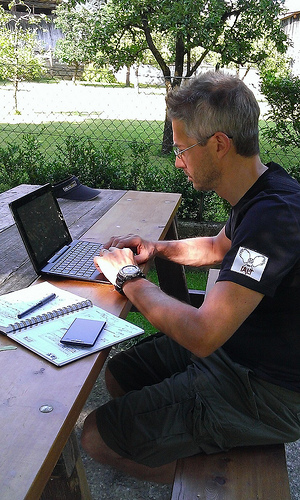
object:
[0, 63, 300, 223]
fence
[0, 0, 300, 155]
trees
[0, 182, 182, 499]
bench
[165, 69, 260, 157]
hair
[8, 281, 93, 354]
spiral notebook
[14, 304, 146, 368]
cover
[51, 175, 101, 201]
black visor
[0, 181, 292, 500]
picnic table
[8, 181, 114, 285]
laptop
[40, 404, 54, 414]
bolt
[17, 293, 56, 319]
pen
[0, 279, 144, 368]
book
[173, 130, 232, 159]
glasses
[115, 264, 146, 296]
watch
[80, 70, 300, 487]
he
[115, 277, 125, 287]
metal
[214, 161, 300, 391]
shirt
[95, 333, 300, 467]
shorts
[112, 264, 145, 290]
wrist